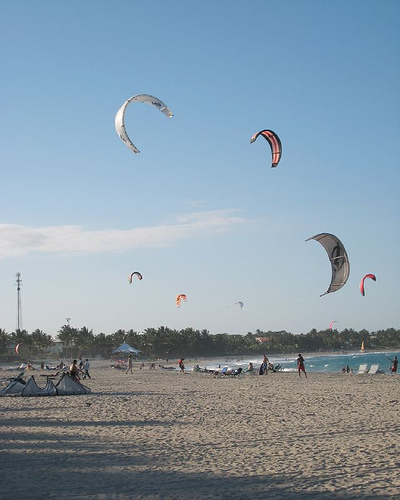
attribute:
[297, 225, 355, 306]
kite — large 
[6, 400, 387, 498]
sand — brown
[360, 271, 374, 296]
kite — red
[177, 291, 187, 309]
kite — red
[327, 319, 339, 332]
kite — red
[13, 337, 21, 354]
kite — red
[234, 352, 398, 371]
water — blue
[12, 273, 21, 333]
tower — large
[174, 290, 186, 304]
kite — yellow